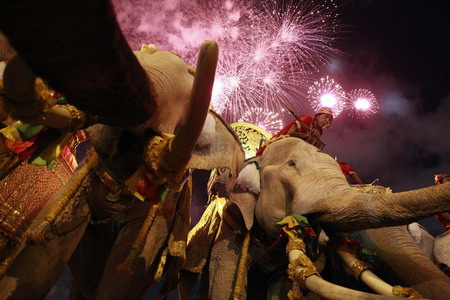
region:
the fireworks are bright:
[232, 34, 338, 90]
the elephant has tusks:
[289, 242, 390, 298]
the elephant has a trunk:
[352, 180, 444, 221]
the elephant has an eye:
[275, 149, 303, 170]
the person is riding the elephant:
[240, 82, 445, 250]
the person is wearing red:
[288, 94, 345, 144]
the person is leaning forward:
[275, 88, 344, 143]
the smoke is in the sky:
[385, 82, 431, 183]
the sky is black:
[387, 14, 426, 52]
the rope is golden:
[223, 237, 256, 298]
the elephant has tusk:
[137, 89, 397, 297]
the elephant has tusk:
[222, 179, 346, 298]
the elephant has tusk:
[233, 112, 364, 281]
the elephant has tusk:
[267, 76, 412, 292]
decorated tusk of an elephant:
[275, 208, 323, 295]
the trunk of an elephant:
[306, 162, 449, 228]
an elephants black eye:
[279, 146, 305, 177]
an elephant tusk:
[153, 32, 225, 206]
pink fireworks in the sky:
[284, 67, 381, 131]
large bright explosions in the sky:
[154, 0, 274, 124]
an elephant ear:
[222, 169, 276, 233]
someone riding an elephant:
[263, 80, 351, 166]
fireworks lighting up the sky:
[138, 0, 400, 166]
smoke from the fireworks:
[314, 71, 432, 178]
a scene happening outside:
[7, 4, 443, 297]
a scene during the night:
[9, 2, 448, 295]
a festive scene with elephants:
[7, 3, 446, 298]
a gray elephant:
[213, 90, 447, 297]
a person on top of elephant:
[250, 90, 343, 180]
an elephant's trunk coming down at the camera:
[4, 1, 212, 159]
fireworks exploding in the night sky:
[93, 0, 399, 156]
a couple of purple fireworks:
[300, 59, 389, 151]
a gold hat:
[301, 90, 347, 121]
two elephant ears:
[199, 92, 268, 231]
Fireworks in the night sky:
[184, 1, 402, 159]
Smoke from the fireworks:
[125, 2, 245, 50]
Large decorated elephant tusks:
[272, 203, 419, 298]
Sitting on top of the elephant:
[243, 68, 360, 194]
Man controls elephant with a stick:
[261, 80, 335, 149]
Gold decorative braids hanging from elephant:
[22, 149, 162, 279]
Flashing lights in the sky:
[191, 3, 394, 154]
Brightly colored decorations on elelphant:
[265, 207, 380, 270]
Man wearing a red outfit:
[247, 107, 342, 161]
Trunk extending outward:
[269, 127, 449, 262]